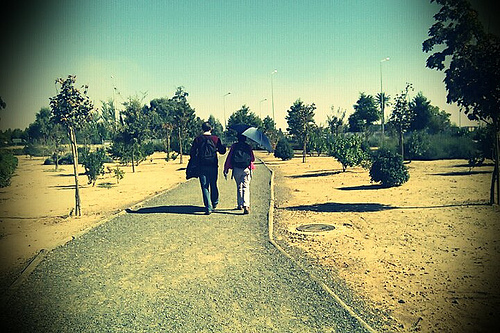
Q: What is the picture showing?
A: It is showing a path.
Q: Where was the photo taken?
A: It was taken at the path.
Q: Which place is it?
A: It is a path.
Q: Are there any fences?
A: No, there are no fences.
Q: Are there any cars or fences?
A: No, there are no fences or cars.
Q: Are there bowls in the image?
A: No, there are no bowls.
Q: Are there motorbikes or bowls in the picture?
A: No, there are no bowls or motorbikes.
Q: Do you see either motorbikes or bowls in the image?
A: No, there are no bowls or motorbikes.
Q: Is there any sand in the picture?
A: Yes, there is sand.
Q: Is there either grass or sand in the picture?
A: Yes, there is sand.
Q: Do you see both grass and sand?
A: No, there is sand but no grass.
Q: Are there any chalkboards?
A: No, there are no chalkboards.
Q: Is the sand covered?
A: Yes, the sand is covered.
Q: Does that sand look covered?
A: Yes, the sand is covered.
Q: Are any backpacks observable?
A: Yes, there is a backpack.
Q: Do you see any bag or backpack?
A: Yes, there is a backpack.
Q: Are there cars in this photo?
A: No, there are no cars.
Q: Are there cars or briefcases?
A: No, there are no cars or briefcases.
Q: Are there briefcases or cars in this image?
A: No, there are no cars or briefcases.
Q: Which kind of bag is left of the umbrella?
A: The bag is a backpack.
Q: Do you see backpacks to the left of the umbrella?
A: Yes, there is a backpack to the left of the umbrella.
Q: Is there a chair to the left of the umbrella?
A: No, there is a backpack to the left of the umbrella.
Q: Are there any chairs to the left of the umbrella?
A: No, there is a backpack to the left of the umbrella.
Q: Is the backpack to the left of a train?
A: No, the backpack is to the left of an umbrella.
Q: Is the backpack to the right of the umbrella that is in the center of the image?
A: No, the backpack is to the left of the umbrella.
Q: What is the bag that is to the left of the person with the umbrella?
A: The bag is a backpack.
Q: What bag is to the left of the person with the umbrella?
A: The bag is a backpack.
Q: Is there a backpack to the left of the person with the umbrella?
A: Yes, there is a backpack to the left of the person.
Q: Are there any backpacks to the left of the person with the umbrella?
A: Yes, there is a backpack to the left of the person.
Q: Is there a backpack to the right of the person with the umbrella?
A: No, the backpack is to the left of the person.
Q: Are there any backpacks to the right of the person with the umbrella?
A: No, the backpack is to the left of the person.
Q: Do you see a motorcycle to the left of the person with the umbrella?
A: No, there is a backpack to the left of the person.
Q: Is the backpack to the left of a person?
A: Yes, the backpack is to the left of a person.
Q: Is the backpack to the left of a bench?
A: No, the backpack is to the left of a person.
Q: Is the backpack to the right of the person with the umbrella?
A: No, the backpack is to the left of the person.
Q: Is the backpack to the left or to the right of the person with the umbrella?
A: The backpack is to the left of the person.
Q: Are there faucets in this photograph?
A: No, there are no faucets.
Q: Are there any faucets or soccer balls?
A: No, there are no faucets or soccer balls.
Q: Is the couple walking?
A: Yes, the couple is walking.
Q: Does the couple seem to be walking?
A: Yes, the couple is walking.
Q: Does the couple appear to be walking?
A: Yes, the couple is walking.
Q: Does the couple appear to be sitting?
A: No, the couple is walking.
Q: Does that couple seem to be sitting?
A: No, the couple is walking.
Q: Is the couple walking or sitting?
A: The couple is walking.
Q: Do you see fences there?
A: No, there are no fences.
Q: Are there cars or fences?
A: No, there are no fences or cars.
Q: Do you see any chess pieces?
A: No, there are no chess pieces.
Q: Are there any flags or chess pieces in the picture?
A: No, there are no chess pieces or flags.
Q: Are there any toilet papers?
A: No, there are no toilet papers.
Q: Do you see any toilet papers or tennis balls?
A: No, there are no toilet papers or tennis balls.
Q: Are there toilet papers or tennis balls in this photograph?
A: No, there are no toilet papers or tennis balls.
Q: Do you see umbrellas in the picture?
A: Yes, there is an umbrella.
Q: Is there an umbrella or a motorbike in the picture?
A: Yes, there is an umbrella.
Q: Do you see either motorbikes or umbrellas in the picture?
A: Yes, there is an umbrella.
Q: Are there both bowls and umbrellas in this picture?
A: No, there is an umbrella but no bowls.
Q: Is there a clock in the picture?
A: No, there are no clocks.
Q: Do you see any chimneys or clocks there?
A: No, there are no clocks or chimneys.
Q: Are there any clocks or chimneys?
A: No, there are no clocks or chimneys.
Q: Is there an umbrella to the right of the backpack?
A: Yes, there is an umbrella to the right of the backpack.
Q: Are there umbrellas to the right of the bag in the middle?
A: Yes, there is an umbrella to the right of the backpack.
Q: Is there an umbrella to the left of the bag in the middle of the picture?
A: No, the umbrella is to the right of the backpack.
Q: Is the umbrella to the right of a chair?
A: No, the umbrella is to the right of the backpack.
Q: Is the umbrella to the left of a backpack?
A: No, the umbrella is to the right of a backpack.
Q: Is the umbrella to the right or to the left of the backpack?
A: The umbrella is to the right of the backpack.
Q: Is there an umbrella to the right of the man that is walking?
A: Yes, there is an umbrella to the right of the man.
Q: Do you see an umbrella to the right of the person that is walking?
A: Yes, there is an umbrella to the right of the man.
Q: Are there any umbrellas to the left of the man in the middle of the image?
A: No, the umbrella is to the right of the man.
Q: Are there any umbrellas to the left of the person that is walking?
A: No, the umbrella is to the right of the man.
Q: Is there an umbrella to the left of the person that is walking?
A: No, the umbrella is to the right of the man.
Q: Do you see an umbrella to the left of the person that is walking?
A: No, the umbrella is to the right of the man.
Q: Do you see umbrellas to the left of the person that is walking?
A: No, the umbrella is to the right of the man.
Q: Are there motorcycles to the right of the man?
A: No, there is an umbrella to the right of the man.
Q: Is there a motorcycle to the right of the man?
A: No, there is an umbrella to the right of the man.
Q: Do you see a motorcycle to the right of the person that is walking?
A: No, there is an umbrella to the right of the man.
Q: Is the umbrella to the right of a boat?
A: No, the umbrella is to the right of the man.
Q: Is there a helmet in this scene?
A: No, there are no helmets.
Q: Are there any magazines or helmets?
A: No, there are no helmets or magazines.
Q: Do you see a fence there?
A: No, there are no fences.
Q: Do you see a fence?
A: No, there are no fences.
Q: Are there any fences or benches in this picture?
A: No, there are no fences or benches.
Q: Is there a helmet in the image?
A: No, there are no helmets.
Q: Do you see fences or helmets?
A: No, there are no helmets or fences.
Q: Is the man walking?
A: Yes, the man is walking.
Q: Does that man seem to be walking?
A: Yes, the man is walking.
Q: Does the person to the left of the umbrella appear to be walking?
A: Yes, the man is walking.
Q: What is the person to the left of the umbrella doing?
A: The man is walking.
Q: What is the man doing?
A: The man is walking.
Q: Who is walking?
A: The man is walking.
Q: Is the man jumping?
A: No, the man is walking.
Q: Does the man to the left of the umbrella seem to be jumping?
A: No, the man is walking.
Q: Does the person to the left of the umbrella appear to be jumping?
A: No, the man is walking.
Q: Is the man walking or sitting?
A: The man is walking.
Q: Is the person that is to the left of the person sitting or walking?
A: The man is walking.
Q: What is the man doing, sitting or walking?
A: The man is walking.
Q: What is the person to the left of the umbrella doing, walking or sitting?
A: The man is walking.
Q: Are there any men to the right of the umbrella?
A: No, the man is to the left of the umbrella.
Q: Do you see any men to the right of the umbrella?
A: No, the man is to the left of the umbrella.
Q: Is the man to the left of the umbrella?
A: Yes, the man is to the left of the umbrella.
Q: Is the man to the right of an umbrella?
A: No, the man is to the left of an umbrella.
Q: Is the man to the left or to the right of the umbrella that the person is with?
A: The man is to the left of the umbrella.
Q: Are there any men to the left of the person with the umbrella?
A: Yes, there is a man to the left of the person.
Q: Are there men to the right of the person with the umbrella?
A: No, the man is to the left of the person.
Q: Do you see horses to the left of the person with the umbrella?
A: No, there is a man to the left of the person.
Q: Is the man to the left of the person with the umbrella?
A: Yes, the man is to the left of the person.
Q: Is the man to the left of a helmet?
A: No, the man is to the left of the person.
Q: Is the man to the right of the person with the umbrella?
A: No, the man is to the left of the person.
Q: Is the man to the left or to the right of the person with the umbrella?
A: The man is to the left of the person.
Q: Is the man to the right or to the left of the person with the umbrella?
A: The man is to the left of the person.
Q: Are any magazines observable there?
A: No, there are no magazines.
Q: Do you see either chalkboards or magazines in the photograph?
A: No, there are no magazines or chalkboards.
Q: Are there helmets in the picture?
A: No, there are no helmets.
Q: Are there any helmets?
A: No, there are no helmets.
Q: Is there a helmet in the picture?
A: No, there are no helmets.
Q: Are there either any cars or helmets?
A: No, there are no helmets or cars.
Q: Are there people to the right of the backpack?
A: Yes, there is a person to the right of the backpack.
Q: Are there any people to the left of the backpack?
A: No, the person is to the right of the backpack.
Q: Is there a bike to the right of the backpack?
A: No, there is a person to the right of the backpack.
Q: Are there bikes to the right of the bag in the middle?
A: No, there is a person to the right of the backpack.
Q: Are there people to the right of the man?
A: Yes, there is a person to the right of the man.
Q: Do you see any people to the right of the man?
A: Yes, there is a person to the right of the man.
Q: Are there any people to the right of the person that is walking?
A: Yes, there is a person to the right of the man.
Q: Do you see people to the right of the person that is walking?
A: Yes, there is a person to the right of the man.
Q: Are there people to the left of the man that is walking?
A: No, the person is to the right of the man.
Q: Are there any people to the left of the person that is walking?
A: No, the person is to the right of the man.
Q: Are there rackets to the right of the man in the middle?
A: No, there is a person to the right of the man.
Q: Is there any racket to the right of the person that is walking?
A: No, there is a person to the right of the man.